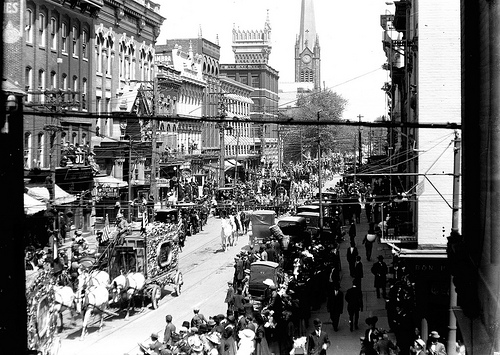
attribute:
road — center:
[24, 169, 343, 354]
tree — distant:
[296, 79, 346, 161]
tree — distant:
[298, 125, 338, 162]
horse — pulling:
[212, 217, 244, 249]